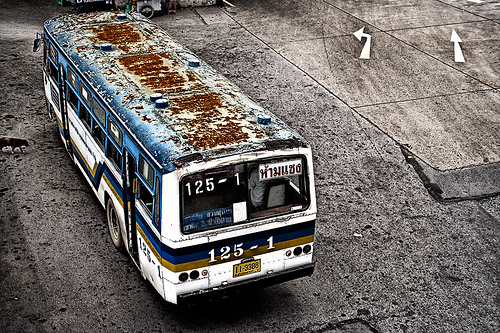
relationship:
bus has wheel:
[23, 28, 363, 305] [88, 205, 135, 249]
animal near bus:
[7, 117, 37, 153] [23, 28, 363, 305]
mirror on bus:
[22, 27, 54, 60] [23, 28, 363, 305]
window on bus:
[160, 172, 256, 236] [23, 28, 363, 305]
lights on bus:
[180, 260, 201, 285] [23, 28, 363, 305]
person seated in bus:
[242, 167, 294, 210] [23, 28, 363, 305]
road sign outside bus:
[122, 4, 166, 23] [23, 28, 363, 305]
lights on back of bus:
[180, 260, 201, 285] [23, 28, 363, 305]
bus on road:
[23, 28, 363, 305] [304, 128, 494, 306]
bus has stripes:
[23, 28, 363, 305] [72, 146, 318, 263]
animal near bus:
[0, 127, 32, 156] [23, 28, 363, 305]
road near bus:
[304, 128, 494, 306] [23, 28, 363, 305]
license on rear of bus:
[227, 246, 270, 286] [23, 28, 363, 305]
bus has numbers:
[23, 28, 363, 305] [187, 176, 248, 202]